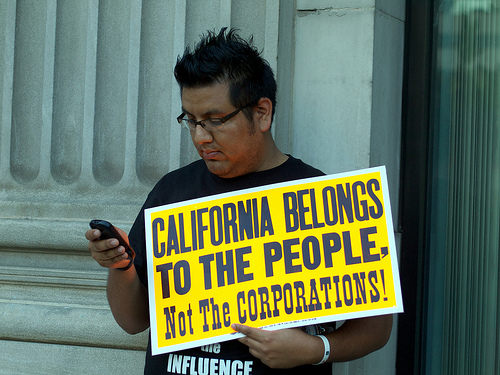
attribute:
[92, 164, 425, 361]
sign — white , yellow , purple 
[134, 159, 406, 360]
sign — yellow, rectangular